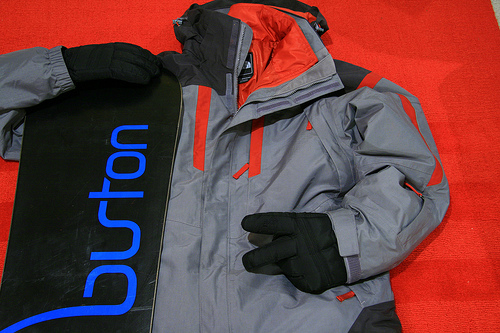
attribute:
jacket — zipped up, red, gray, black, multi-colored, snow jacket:
[2, 0, 449, 331]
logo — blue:
[1, 120, 159, 332]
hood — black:
[172, 0, 328, 44]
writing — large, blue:
[75, 107, 150, 330]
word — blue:
[0, 123, 150, 330]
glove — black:
[234, 206, 365, 309]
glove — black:
[63, 30, 165, 103]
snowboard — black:
[77, 119, 152, 269]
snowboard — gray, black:
[22, 25, 178, 329]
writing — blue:
[1, 112, 160, 332]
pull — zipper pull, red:
[232, 163, 248, 181]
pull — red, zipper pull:
[336, 290, 355, 303]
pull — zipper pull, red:
[305, 121, 312, 130]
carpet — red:
[2, 7, 497, 320]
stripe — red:
[366, 72, 471, 209]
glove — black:
[229, 197, 347, 293]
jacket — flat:
[9, 25, 453, 329]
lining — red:
[258, 29, 317, 83]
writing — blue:
[21, 119, 153, 331]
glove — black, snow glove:
[239, 214, 353, 294]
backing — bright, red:
[342, 7, 494, 328]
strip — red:
[364, 69, 451, 186]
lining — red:
[240, 7, 317, 87]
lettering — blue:
[0, 123, 148, 331]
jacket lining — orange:
[227, 1, 317, 105]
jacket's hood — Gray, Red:
[171, 0, 325, 60]